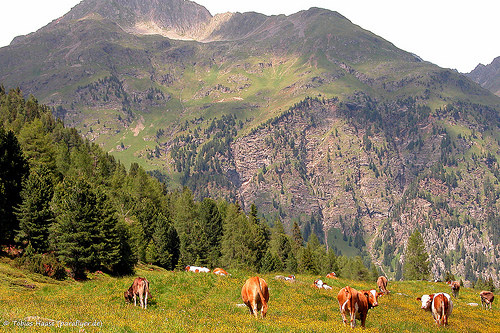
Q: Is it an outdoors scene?
A: Yes, it is outdoors.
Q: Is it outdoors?
A: Yes, it is outdoors.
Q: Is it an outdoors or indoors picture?
A: It is outdoors.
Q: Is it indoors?
A: No, it is outdoors.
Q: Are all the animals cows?
A: Yes, all the animals are cows.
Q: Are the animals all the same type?
A: Yes, all the animals are cows.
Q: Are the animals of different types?
A: No, all the animals are cows.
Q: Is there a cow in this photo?
A: Yes, there is a cow.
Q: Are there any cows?
A: Yes, there is a cow.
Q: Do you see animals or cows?
A: Yes, there is a cow.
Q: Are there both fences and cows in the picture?
A: No, there is a cow but no fences.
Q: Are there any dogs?
A: No, there are no dogs.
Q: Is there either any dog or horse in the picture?
A: No, there are no dogs or horses.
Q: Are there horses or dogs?
A: No, there are no dogs or horses.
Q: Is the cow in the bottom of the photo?
A: Yes, the cow is in the bottom of the image.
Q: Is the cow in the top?
A: No, the cow is in the bottom of the image.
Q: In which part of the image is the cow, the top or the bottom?
A: The cow is in the bottom of the image.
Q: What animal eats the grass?
A: The cow eats the grass.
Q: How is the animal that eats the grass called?
A: The animal is a cow.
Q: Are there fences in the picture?
A: No, there are no fences.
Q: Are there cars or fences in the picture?
A: No, there are no fences or cars.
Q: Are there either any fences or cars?
A: No, there are no fences or cars.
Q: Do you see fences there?
A: No, there are no fences.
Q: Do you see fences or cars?
A: No, there are no fences or cars.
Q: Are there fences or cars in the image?
A: No, there are no fences or cars.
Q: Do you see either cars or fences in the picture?
A: No, there are no fences or cars.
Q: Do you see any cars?
A: No, there are no cars.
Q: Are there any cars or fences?
A: No, there are no cars or fences.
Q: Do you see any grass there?
A: Yes, there is grass.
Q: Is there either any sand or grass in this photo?
A: Yes, there is grass.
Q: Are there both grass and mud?
A: No, there is grass but no mud.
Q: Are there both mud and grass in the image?
A: No, there is grass but no mud.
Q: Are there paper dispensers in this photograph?
A: No, there are no paper dispensers.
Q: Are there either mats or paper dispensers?
A: No, there are no paper dispensers or mats.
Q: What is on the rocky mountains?
A: The grass is on the mountains.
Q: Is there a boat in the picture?
A: No, there are no boats.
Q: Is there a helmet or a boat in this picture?
A: No, there are no boats or helmets.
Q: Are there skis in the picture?
A: No, there are no skis.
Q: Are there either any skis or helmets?
A: No, there are no skis or helmets.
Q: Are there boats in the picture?
A: No, there are no boats.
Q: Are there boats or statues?
A: No, there are no boats or statues.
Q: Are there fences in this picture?
A: No, there are no fences.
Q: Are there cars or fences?
A: No, there are no fences or cars.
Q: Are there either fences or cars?
A: No, there are no fences or cars.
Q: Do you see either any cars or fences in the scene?
A: No, there are no fences or cars.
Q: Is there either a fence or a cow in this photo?
A: Yes, there is a cow.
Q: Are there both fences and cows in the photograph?
A: No, there is a cow but no fences.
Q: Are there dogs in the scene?
A: No, there are no dogs.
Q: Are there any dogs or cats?
A: No, there are no dogs or cats.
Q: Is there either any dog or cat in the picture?
A: No, there are no dogs or cats.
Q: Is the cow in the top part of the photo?
A: No, the cow is in the bottom of the image.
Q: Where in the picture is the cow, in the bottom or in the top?
A: The cow is in the bottom of the image.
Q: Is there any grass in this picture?
A: Yes, there is grass.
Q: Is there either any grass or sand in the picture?
A: Yes, there is grass.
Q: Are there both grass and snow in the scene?
A: No, there is grass but no snow.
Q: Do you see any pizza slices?
A: No, there are no pizza slices.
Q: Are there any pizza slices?
A: No, there are no pizza slices.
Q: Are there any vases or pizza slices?
A: No, there are no pizza slices or vases.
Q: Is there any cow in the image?
A: Yes, there is a cow.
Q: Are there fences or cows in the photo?
A: Yes, there is a cow.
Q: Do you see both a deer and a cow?
A: No, there is a cow but no deer.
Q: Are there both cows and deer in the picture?
A: No, there is a cow but no deer.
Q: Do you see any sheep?
A: No, there are no sheep.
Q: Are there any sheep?
A: No, there are no sheep.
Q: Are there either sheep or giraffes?
A: No, there are no sheep or giraffes.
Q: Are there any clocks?
A: No, there are no clocks.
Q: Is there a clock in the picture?
A: No, there are no clocks.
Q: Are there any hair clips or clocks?
A: No, there are no clocks or hair clips.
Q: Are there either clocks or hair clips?
A: No, there are no clocks or hair clips.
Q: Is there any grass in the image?
A: Yes, there is grass.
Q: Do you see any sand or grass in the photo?
A: Yes, there is grass.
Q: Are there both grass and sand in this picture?
A: No, there is grass but no sand.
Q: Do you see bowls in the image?
A: No, there are no bowls.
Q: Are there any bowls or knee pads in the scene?
A: No, there are no bowls or knee pads.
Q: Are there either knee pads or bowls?
A: No, there are no bowls or knee pads.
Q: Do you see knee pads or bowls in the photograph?
A: No, there are no bowls or knee pads.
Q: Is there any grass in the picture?
A: Yes, there is grass.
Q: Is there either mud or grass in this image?
A: Yes, there is grass.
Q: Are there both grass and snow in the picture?
A: No, there is grass but no snow.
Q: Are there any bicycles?
A: No, there are no bicycles.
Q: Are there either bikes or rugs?
A: No, there are no bikes or rugs.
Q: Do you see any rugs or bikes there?
A: No, there are no bikes or rugs.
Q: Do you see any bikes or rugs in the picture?
A: No, there are no bikes or rugs.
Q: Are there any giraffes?
A: No, there are no giraffes.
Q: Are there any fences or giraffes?
A: No, there are no giraffes or fences.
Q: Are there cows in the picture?
A: Yes, there is a cow.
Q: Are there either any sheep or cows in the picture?
A: Yes, there is a cow.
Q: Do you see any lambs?
A: No, there are no lambs.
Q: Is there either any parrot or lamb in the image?
A: No, there are no lambs or parrots.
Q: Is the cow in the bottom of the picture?
A: Yes, the cow is in the bottom of the image.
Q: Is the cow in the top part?
A: No, the cow is in the bottom of the image.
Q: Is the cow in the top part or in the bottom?
A: The cow is in the bottom of the image.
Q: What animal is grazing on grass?
A: The cow is grazing on grass.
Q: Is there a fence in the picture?
A: No, there are no fences.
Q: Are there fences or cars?
A: No, there are no fences or cars.